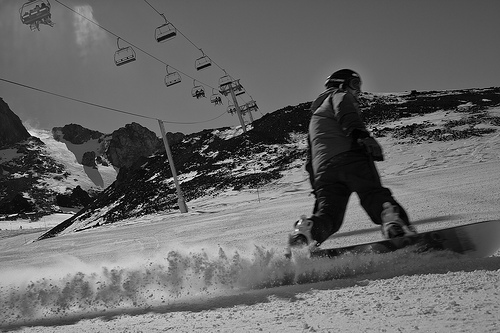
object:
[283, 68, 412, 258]
person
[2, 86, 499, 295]
snow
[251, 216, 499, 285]
snowboard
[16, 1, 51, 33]
lift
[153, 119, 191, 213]
pole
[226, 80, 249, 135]
pole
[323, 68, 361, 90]
helmet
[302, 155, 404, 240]
pants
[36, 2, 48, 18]
person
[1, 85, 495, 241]
mountain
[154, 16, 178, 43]
car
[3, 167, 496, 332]
ground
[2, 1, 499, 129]
sky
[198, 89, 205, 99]
person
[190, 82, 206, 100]
chair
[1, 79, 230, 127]
wires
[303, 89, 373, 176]
jacket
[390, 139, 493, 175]
tracks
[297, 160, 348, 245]
leg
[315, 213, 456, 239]
shadow